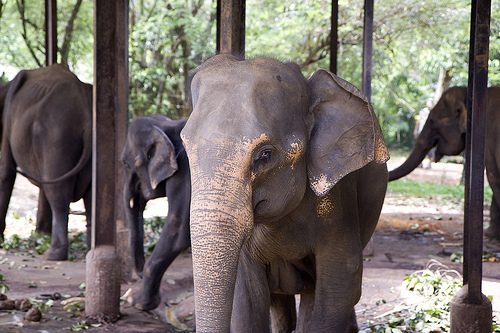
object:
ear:
[301, 69, 392, 198]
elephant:
[177, 48, 395, 332]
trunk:
[185, 149, 253, 333]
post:
[359, 0, 376, 96]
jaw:
[256, 193, 300, 225]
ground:
[406, 193, 455, 330]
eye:
[250, 144, 275, 166]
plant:
[375, 30, 429, 106]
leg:
[119, 202, 191, 311]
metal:
[85, 156, 132, 247]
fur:
[221, 78, 262, 112]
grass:
[409, 180, 455, 197]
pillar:
[85, 0, 134, 248]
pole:
[214, 0, 248, 56]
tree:
[392, 0, 500, 159]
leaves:
[382, 113, 413, 141]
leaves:
[396, 271, 417, 297]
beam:
[462, 0, 487, 301]